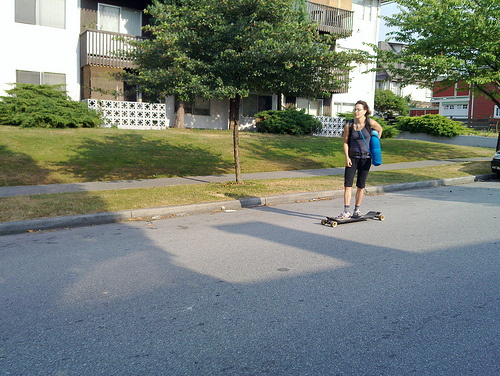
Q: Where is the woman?
A: In the street.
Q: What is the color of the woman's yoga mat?
A: Blue.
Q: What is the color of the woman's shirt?
A: Gray.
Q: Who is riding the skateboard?
A: A woman.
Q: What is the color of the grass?
A: Green.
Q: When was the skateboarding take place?
A: Daytime.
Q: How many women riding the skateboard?
A: One.